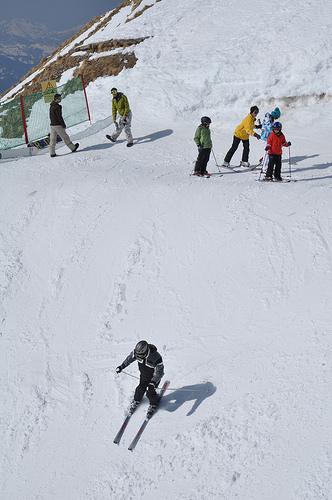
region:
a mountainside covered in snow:
[9, 5, 331, 291]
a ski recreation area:
[10, 65, 311, 493]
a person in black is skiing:
[108, 338, 172, 457]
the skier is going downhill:
[106, 335, 207, 458]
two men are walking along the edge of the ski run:
[39, 83, 137, 156]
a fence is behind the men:
[4, 65, 91, 148]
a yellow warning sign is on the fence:
[36, 74, 62, 102]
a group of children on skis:
[190, 98, 294, 186]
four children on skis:
[193, 99, 301, 189]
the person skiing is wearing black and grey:
[100, 339, 182, 463]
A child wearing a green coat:
[190, 122, 224, 154]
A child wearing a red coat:
[265, 129, 291, 165]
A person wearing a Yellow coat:
[232, 109, 262, 146]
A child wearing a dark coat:
[41, 96, 73, 131]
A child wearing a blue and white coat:
[261, 111, 280, 145]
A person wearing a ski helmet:
[125, 334, 153, 362]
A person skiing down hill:
[93, 333, 226, 481]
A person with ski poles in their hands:
[105, 360, 219, 415]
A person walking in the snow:
[98, 84, 150, 167]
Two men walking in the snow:
[36, 79, 153, 172]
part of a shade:
[191, 408, 197, 423]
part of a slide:
[133, 437, 137, 446]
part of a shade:
[183, 388, 202, 421]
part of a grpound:
[249, 408, 274, 450]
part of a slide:
[133, 426, 146, 446]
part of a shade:
[182, 399, 195, 429]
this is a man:
[100, 83, 153, 145]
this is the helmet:
[126, 337, 153, 357]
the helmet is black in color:
[203, 114, 210, 120]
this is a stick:
[286, 144, 309, 168]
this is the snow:
[209, 292, 316, 429]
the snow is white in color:
[223, 285, 282, 353]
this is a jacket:
[271, 137, 280, 147]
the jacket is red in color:
[269, 139, 276, 145]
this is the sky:
[8, 5, 70, 31]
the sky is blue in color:
[33, 6, 63, 12]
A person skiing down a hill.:
[108, 340, 181, 455]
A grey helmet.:
[133, 339, 147, 356]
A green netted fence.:
[2, 79, 91, 152]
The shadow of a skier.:
[159, 380, 217, 415]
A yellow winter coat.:
[234, 115, 254, 139]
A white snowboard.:
[3, 147, 37, 159]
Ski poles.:
[257, 144, 294, 182]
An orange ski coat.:
[265, 133, 289, 153]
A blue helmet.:
[272, 121, 282, 127]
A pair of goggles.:
[109, 89, 117, 94]